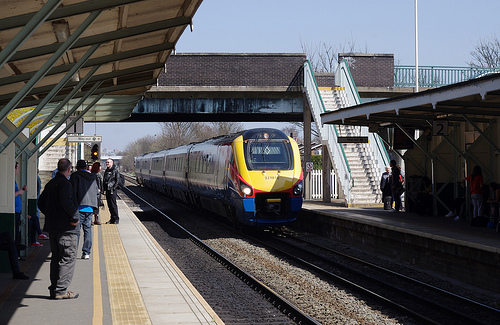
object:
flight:
[307, 62, 396, 206]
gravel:
[292, 284, 347, 307]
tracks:
[133, 190, 315, 325]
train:
[128, 123, 321, 223]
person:
[72, 158, 97, 260]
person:
[101, 157, 123, 226]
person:
[465, 164, 487, 226]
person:
[388, 160, 405, 213]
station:
[1, 2, 496, 323]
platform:
[28, 169, 216, 324]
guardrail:
[391, 63, 496, 93]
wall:
[295, 58, 356, 209]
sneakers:
[81, 251, 90, 261]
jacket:
[36, 172, 84, 231]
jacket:
[72, 170, 104, 213]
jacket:
[103, 166, 123, 194]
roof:
[4, 3, 201, 121]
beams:
[0, 0, 56, 60]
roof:
[320, 69, 500, 131]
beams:
[370, 129, 408, 164]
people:
[38, 157, 78, 299]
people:
[378, 166, 395, 210]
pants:
[105, 184, 120, 224]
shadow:
[123, 178, 247, 239]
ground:
[193, 213, 496, 322]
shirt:
[465, 170, 487, 196]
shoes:
[445, 211, 456, 218]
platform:
[307, 183, 497, 249]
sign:
[336, 134, 369, 144]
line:
[86, 224, 146, 325]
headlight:
[240, 184, 255, 197]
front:
[222, 125, 309, 228]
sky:
[190, 1, 496, 70]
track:
[290, 232, 500, 325]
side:
[132, 140, 240, 193]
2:
[434, 122, 447, 135]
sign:
[431, 118, 449, 136]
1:
[67, 118, 79, 132]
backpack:
[114, 172, 125, 190]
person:
[27, 167, 49, 250]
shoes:
[30, 241, 45, 248]